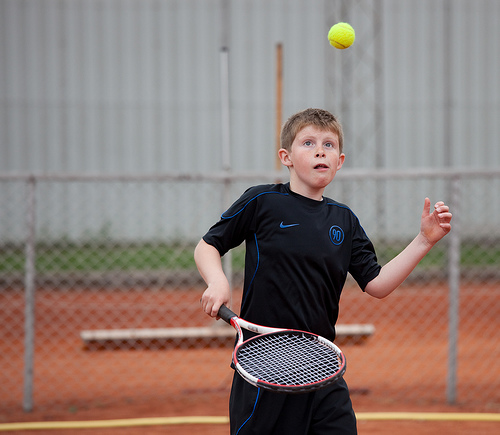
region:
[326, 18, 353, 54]
a bright yellow tennis ball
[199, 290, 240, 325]
a handle with black grip tape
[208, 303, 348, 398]
a red and white tennis racket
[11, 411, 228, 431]
a yellow line on the ground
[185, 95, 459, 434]
a boy playing tennis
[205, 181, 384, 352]
a black and blue nike shirt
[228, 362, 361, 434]
a pair of black athletic shorts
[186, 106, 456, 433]
a young boy with blue eyes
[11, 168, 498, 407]
a metal chain link fence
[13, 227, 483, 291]
a patch of grass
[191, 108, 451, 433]
a young boy playing tennis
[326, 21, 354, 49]
a yellow tennis ball in the air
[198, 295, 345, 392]
a tennis racket in the boy's hand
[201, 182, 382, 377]
a black athletic shirt on the boy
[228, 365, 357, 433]
black athletic shorts on the boy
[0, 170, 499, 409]
a chain link fence behind the boy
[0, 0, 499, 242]
a building behind the boy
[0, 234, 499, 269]
a small strip of green grass behind the boy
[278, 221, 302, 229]
Nike logo on boy's shirt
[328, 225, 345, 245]
blue number on boy's shirt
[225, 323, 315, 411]
tennis racket is red and white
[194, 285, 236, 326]
boy is holding a tennis racket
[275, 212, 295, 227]
blue nike logo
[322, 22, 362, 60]
tennis ball is bright yellow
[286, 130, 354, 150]
boy is looking at the tennis ball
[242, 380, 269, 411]
blue stripe on the shorts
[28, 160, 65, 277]
chain link fence behind the boy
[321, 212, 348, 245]
90 is on his shirt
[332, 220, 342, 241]
90 is in a circle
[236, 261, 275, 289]
blue stripe on his shirt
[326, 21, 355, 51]
The tennis ball is airborne.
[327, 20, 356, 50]
The tennis ball is yellow.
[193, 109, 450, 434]
The boy is playing tennis.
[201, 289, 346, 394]
The boy holds a tennis racquet.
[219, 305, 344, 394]
The tennis racquet is red.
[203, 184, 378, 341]
The boy's top is black.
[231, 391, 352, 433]
The boy's shorts are black.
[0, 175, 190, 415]
A chain link fence is behind the boy.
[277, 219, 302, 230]
The Nike logo is on the shirt.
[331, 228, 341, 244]
The number 90 is on the shirt.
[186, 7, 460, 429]
boy playing tennis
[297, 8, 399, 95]
green tennis ball in air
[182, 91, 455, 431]
boy holding tennis racket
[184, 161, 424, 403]
black and blue tennis shirt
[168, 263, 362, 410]
red and white tennis racket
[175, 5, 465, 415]
young tennis player looking at ball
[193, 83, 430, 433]
young male playing tennis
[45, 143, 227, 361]
chain link fence in background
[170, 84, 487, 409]
young white boy playing tennis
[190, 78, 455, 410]
boy trying to hit ball with racket